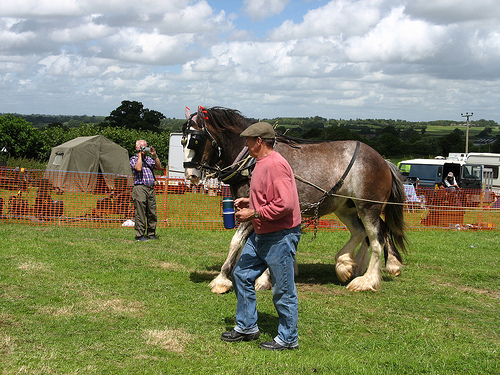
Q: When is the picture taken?
A: Daytime.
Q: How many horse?
A: 1.